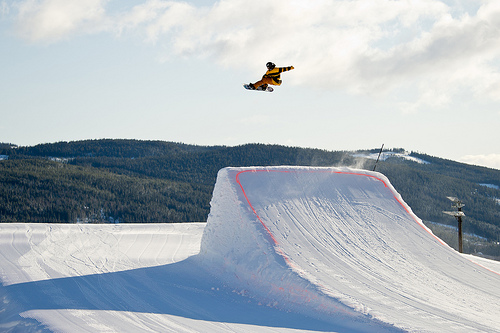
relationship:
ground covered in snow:
[1, 165, 498, 331] [2, 167, 495, 330]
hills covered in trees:
[98, 138, 218, 212] [7, 143, 206, 203]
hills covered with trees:
[98, 138, 218, 212] [66, 136, 166, 208]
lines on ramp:
[220, 165, 500, 328] [195, 163, 498, 332]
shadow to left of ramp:
[0, 247, 371, 330] [201, 157, 353, 254]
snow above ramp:
[359, 147, 426, 164] [195, 163, 498, 332]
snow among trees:
[359, 147, 426, 164] [334, 142, 446, 174]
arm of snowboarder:
[277, 64, 294, 73] [241, 57, 293, 94]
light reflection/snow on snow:
[42, 219, 192, 264] [8, 226, 295, 331]